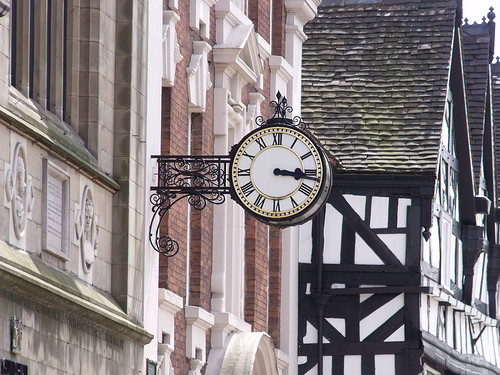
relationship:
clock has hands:
[230, 123, 333, 226] [273, 167, 322, 181]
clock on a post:
[230, 123, 333, 226] [150, 154, 233, 257]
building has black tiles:
[0, 1, 154, 374] [1, 359, 28, 374]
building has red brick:
[146, 0, 322, 374] [157, 0, 287, 374]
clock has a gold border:
[230, 123, 333, 226] [232, 126, 325, 218]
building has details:
[299, 1, 500, 375] [186, 41, 216, 113]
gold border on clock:
[232, 126, 325, 218] [230, 123, 333, 226]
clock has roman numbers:
[230, 123, 333, 226] [238, 133, 318, 212]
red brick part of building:
[157, 0, 287, 374] [146, 0, 322, 374]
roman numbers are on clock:
[238, 133, 318, 212] [230, 123, 333, 226]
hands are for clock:
[273, 167, 322, 181] [230, 123, 333, 226]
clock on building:
[230, 123, 333, 226] [146, 0, 322, 374]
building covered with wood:
[299, 1, 500, 375] [407, 205, 421, 266]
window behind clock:
[215, 89, 252, 330] [230, 123, 333, 226]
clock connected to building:
[230, 123, 333, 226] [146, 0, 322, 374]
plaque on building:
[43, 157, 72, 260] [0, 1, 154, 374]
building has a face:
[0, 1, 154, 374] [84, 198, 97, 264]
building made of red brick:
[146, 0, 322, 374] [157, 0, 287, 374]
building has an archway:
[146, 0, 322, 374] [204, 331, 276, 374]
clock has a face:
[230, 123, 333, 226] [232, 126, 325, 218]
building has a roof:
[299, 1, 500, 375] [301, 0, 499, 209]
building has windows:
[0, 1, 154, 374] [11, 0, 70, 124]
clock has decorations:
[230, 123, 333, 226] [256, 90, 306, 129]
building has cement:
[0, 1, 154, 374] [0, 0, 154, 374]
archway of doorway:
[204, 331, 276, 374] [249, 353, 271, 373]